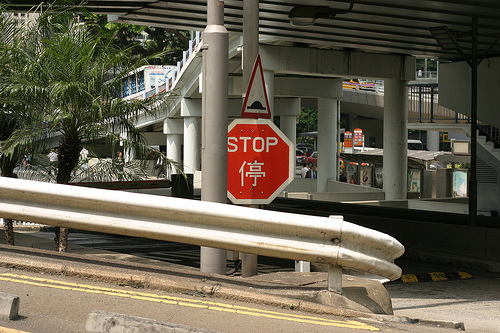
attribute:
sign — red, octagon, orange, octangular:
[228, 119, 296, 206]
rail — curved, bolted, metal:
[1, 172, 405, 295]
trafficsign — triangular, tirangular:
[239, 52, 272, 118]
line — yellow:
[1, 270, 374, 332]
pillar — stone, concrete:
[382, 78, 407, 202]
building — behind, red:
[1, 10, 89, 66]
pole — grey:
[242, 0, 260, 278]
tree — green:
[2, 4, 172, 249]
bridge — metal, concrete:
[0, 38, 204, 167]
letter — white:
[227, 134, 278, 154]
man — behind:
[305, 162, 319, 177]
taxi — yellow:
[342, 76, 375, 93]